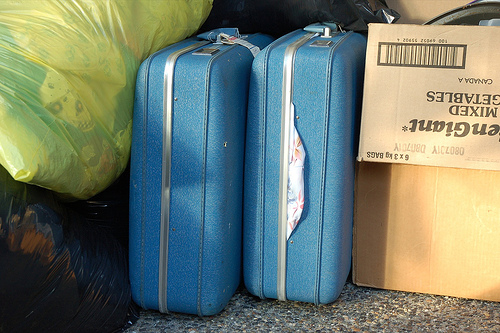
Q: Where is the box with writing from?
A: Canada.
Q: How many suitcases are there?
A: Two.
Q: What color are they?
A: Blue.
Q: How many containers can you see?
A: Six.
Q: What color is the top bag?
A: Yellow.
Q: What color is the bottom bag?
A: Black.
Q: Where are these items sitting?
A: On the ground.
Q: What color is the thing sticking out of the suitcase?
A: White.